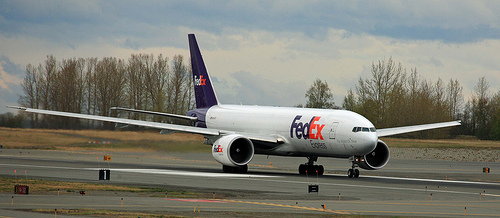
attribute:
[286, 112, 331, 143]
logo — colorful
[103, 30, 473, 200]
airplane — white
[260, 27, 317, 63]
clouds — gray, white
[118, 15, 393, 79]
sky — overcast, cloudy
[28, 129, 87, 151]
grass — brown, dead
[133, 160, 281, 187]
lines — white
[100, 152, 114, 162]
flags — orange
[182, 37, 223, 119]
tail — blue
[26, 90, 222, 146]
wing — white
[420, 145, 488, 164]
rocks — gray